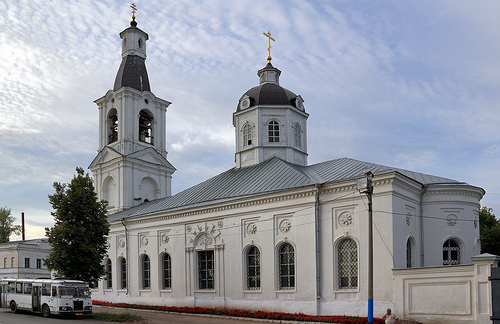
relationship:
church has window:
[108, 157, 420, 225] [332, 235, 357, 295]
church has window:
[108, 157, 420, 225] [278, 243, 292, 290]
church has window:
[108, 157, 420, 225] [246, 248, 259, 292]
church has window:
[108, 157, 420, 225] [198, 251, 215, 287]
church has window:
[108, 157, 420, 225] [161, 257, 170, 288]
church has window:
[108, 157, 420, 225] [139, 257, 149, 289]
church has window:
[108, 157, 420, 225] [117, 258, 128, 290]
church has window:
[108, 157, 420, 225] [104, 261, 111, 288]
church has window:
[108, 157, 420, 225] [408, 242, 415, 271]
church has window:
[108, 157, 420, 225] [444, 242, 457, 267]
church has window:
[108, 157, 420, 225] [267, 121, 280, 143]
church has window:
[108, 157, 420, 225] [294, 125, 302, 147]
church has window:
[108, 157, 420, 225] [242, 124, 253, 147]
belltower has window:
[114, 31, 150, 209] [138, 38, 144, 51]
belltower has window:
[114, 31, 150, 209] [122, 38, 128, 49]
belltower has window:
[114, 31, 150, 209] [140, 111, 151, 145]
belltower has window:
[114, 31, 150, 209] [108, 112, 118, 141]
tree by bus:
[60, 189, 97, 272] [9, 279, 88, 314]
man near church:
[384, 309, 398, 322] [108, 157, 420, 225]